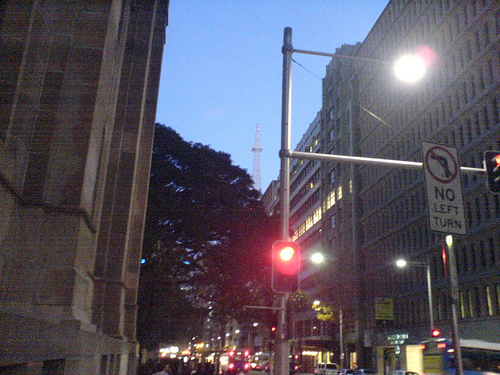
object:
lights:
[146, 328, 340, 369]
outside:
[0, 0, 497, 365]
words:
[434, 186, 462, 229]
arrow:
[430, 154, 449, 178]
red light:
[275, 241, 302, 275]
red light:
[270, 326, 277, 332]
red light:
[431, 329, 441, 337]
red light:
[494, 154, 500, 167]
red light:
[294, 355, 299, 360]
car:
[221, 349, 250, 372]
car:
[314, 363, 338, 373]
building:
[0, 0, 169, 375]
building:
[248, 1, 499, 362]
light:
[311, 253, 325, 264]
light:
[396, 259, 407, 267]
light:
[271, 240, 300, 294]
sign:
[423, 139, 471, 236]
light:
[394, 56, 426, 83]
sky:
[178, 3, 267, 128]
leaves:
[195, 150, 203, 158]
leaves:
[211, 177, 222, 190]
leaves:
[205, 217, 235, 233]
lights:
[288, 185, 343, 241]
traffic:
[192, 339, 269, 374]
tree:
[138, 122, 295, 353]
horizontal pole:
[286, 45, 395, 64]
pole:
[270, 21, 292, 375]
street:
[140, 329, 394, 375]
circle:
[425, 146, 459, 184]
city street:
[149, 349, 379, 374]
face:
[357, 0, 496, 339]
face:
[285, 42, 358, 337]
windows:
[371, 172, 415, 262]